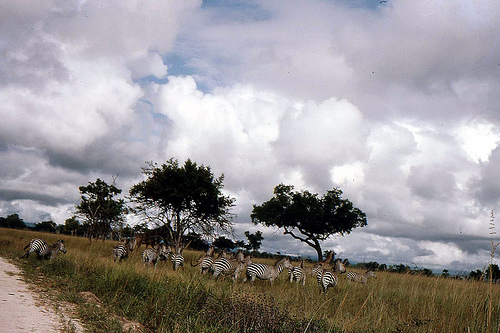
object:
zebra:
[240, 254, 295, 289]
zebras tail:
[21, 237, 35, 248]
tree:
[135, 176, 210, 224]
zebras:
[68, 216, 392, 304]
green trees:
[75, 180, 124, 245]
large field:
[1, 228, 499, 330]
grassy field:
[0, 227, 499, 332]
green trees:
[118, 158, 238, 251]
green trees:
[252, 182, 364, 264]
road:
[1, 276, 38, 323]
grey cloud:
[0, 2, 194, 194]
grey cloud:
[205, 3, 499, 133]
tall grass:
[84, 250, 488, 328]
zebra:
[318, 254, 343, 295]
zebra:
[172, 245, 184, 271]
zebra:
[32, 225, 67, 259]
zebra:
[346, 263, 380, 287]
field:
[1, 230, 499, 329]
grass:
[65, 256, 498, 325]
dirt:
[1, 260, 88, 331]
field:
[90, 252, 260, 332]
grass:
[375, 261, 415, 296]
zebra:
[318, 254, 346, 290]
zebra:
[203, 250, 244, 271]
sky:
[258, 59, 435, 139]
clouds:
[370, 130, 465, 262]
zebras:
[150, 237, 345, 308]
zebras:
[20, 229, 391, 314]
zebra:
[310, 254, 352, 294]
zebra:
[20, 235, 70, 260]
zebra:
[110, 240, 133, 264]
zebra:
[207, 248, 246, 280]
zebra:
[313, 259, 347, 291]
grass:
[176, 273, 401, 328]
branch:
[247, 185, 370, 238]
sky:
[1, 1, 498, 272]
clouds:
[1, 2, 166, 152]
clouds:
[269, 29, 402, 128]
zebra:
[247, 258, 294, 283]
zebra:
[289, 259, 304, 284]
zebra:
[169, 247, 184, 267]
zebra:
[347, 268, 377, 285]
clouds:
[277, 97, 363, 161]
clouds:
[0, 1, 496, 274]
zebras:
[107, 242, 379, 289]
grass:
[325, 281, 446, 321]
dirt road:
[0, 250, 83, 330]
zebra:
[18, 233, 70, 266]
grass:
[2, 227, 497, 331]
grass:
[28, 234, 498, 331]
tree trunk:
[313, 242, 323, 262]